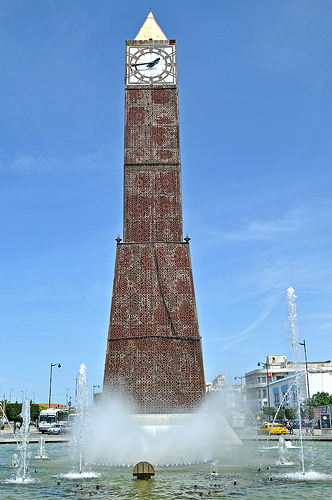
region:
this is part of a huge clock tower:
[103, 14, 204, 180]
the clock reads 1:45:
[121, 35, 186, 91]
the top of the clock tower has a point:
[115, 11, 181, 91]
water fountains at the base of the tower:
[20, 372, 312, 478]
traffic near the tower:
[33, 401, 296, 436]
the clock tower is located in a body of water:
[20, 394, 298, 469]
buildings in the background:
[238, 358, 328, 432]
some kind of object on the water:
[127, 458, 169, 488]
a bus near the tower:
[33, 406, 67, 434]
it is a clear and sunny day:
[12, 174, 303, 375]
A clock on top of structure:
[118, 31, 194, 94]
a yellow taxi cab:
[253, 420, 288, 437]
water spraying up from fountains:
[6, 359, 322, 498]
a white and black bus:
[25, 401, 78, 434]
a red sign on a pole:
[266, 370, 275, 381]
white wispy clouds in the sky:
[169, 196, 327, 339]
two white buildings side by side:
[241, 342, 331, 433]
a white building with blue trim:
[267, 365, 322, 428]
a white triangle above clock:
[132, 8, 182, 42]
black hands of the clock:
[131, 56, 162, 73]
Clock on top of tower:
[113, 10, 186, 96]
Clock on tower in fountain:
[74, 3, 240, 468]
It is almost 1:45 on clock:
[114, 31, 181, 91]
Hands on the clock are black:
[133, 53, 160, 69]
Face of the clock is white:
[123, 37, 175, 84]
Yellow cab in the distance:
[254, 422, 289, 437]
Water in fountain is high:
[56, 363, 107, 485]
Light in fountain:
[123, 451, 162, 481]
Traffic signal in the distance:
[252, 360, 276, 385]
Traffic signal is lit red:
[260, 369, 274, 385]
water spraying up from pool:
[18, 288, 322, 480]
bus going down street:
[36, 407, 67, 430]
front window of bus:
[36, 414, 57, 419]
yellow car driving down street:
[261, 418, 288, 432]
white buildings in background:
[239, 347, 325, 421]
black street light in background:
[46, 357, 64, 408]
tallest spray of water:
[272, 275, 313, 477]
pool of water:
[2, 436, 328, 498]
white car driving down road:
[50, 424, 69, 435]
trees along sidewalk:
[6, 395, 42, 427]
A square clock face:
[122, 36, 178, 89]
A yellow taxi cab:
[256, 419, 286, 435]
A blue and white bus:
[36, 405, 75, 434]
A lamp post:
[45, 358, 63, 407]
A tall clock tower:
[97, 4, 209, 409]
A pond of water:
[0, 435, 331, 499]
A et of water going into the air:
[285, 278, 307, 478]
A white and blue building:
[262, 366, 330, 427]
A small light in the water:
[129, 460, 156, 479]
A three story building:
[238, 351, 330, 424]